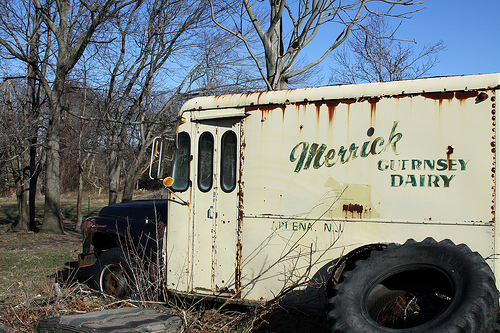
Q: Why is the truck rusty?
A: Because it's old.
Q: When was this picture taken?
A: During the day.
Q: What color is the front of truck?
A: Black.